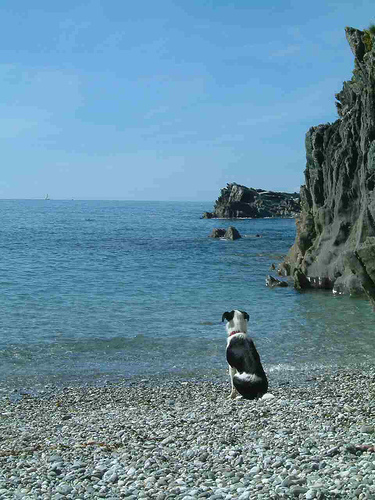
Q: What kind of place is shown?
A: It is a sea.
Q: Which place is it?
A: It is a sea.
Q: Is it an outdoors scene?
A: Yes, it is outdoors.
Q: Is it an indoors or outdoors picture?
A: It is outdoors.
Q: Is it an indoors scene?
A: No, it is outdoors.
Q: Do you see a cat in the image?
A: No, there are no cats.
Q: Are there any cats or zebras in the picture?
A: No, there are no cats or zebras.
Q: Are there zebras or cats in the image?
A: No, there are no cats or zebras.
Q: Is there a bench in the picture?
A: No, there are no benches.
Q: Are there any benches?
A: No, there are no benches.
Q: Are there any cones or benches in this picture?
A: No, there are no benches or cones.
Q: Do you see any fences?
A: No, there are no fences.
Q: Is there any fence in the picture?
A: No, there are no fences.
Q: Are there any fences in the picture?
A: No, there are no fences.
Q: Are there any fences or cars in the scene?
A: No, there are no fences or cars.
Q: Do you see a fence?
A: No, there are no fences.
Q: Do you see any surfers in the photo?
A: No, there are no surfers.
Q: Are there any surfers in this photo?
A: No, there are no surfers.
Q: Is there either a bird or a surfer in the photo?
A: No, there are no surfers or birds.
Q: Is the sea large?
A: Yes, the sea is large.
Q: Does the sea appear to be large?
A: Yes, the sea is large.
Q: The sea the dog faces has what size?
A: The sea is large.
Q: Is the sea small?
A: No, the sea is large.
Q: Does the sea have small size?
A: No, the sea is large.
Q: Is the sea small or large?
A: The sea is large.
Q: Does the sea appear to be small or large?
A: The sea is large.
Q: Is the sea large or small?
A: The sea is large.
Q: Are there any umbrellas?
A: No, there are no umbrellas.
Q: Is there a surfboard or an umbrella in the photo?
A: No, there are no umbrellas or surfboards.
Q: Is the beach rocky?
A: Yes, the beach is rocky.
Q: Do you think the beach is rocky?
A: Yes, the beach is rocky.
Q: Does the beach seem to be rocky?
A: Yes, the beach is rocky.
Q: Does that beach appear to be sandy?
A: No, the beach is rocky.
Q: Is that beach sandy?
A: No, the beach is rocky.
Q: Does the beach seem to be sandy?
A: No, the beach is rocky.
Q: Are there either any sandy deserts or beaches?
A: No, there is a beach but it is rocky.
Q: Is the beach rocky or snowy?
A: The beach is rocky.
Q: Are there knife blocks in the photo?
A: No, there are no knife blocks.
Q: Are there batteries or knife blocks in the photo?
A: No, there are no knife blocks or batteries.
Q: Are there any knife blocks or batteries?
A: No, there are no knife blocks or batteries.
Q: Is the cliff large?
A: Yes, the cliff is large.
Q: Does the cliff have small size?
A: No, the cliff is large.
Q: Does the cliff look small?
A: No, the cliff is large.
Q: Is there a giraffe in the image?
A: No, there are no giraffes.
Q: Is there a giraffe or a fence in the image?
A: No, there are no giraffes or fences.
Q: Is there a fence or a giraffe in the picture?
A: No, there are no giraffes or fences.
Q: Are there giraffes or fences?
A: No, there are no giraffes or fences.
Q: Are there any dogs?
A: Yes, there is a dog.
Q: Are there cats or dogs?
A: Yes, there is a dog.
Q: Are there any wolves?
A: No, there are no wolves.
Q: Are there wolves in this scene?
A: No, there are no wolves.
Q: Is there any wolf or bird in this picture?
A: No, there are no wolves or birds.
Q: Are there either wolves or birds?
A: No, there are no wolves or birds.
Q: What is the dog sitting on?
A: The dog is sitting on the rocks.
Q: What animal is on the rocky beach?
A: The animal is a dog.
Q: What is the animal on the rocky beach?
A: The animal is a dog.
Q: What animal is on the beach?
A: The animal is a dog.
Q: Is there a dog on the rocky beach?
A: Yes, there is a dog on the beach.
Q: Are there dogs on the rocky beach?
A: Yes, there is a dog on the beach.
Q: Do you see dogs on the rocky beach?
A: Yes, there is a dog on the beach.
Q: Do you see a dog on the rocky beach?
A: Yes, there is a dog on the beach.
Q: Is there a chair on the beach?
A: No, there is a dog on the beach.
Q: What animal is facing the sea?
A: The animal is a dog.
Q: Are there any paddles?
A: No, there are no paddles.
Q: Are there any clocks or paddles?
A: No, there are no paddles or clocks.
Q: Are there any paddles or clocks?
A: No, there are no paddles or clocks.